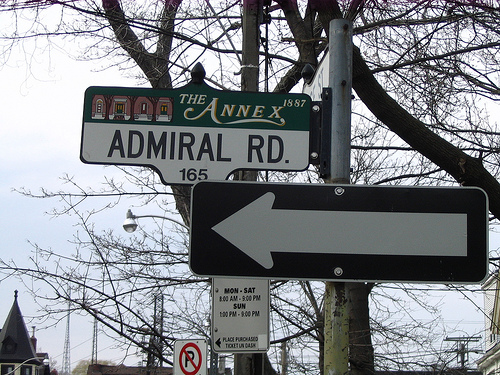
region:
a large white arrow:
[217, 194, 470, 271]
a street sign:
[78, 80, 313, 185]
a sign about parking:
[211, 278, 273, 352]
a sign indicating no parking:
[171, 340, 211, 374]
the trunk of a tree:
[319, 281, 376, 373]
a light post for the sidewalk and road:
[118, 204, 189, 241]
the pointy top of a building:
[0, 301, 42, 373]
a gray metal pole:
[321, 17, 358, 182]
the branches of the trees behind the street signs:
[25, 0, 498, 371]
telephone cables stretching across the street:
[243, 326, 480, 363]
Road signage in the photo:
[111, 100, 361, 267]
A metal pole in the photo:
[323, 72, 361, 138]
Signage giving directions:
[196, 180, 441, 270]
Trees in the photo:
[378, 25, 455, 126]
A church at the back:
[1, 281, 41, 373]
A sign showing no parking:
[165, 330, 211, 373]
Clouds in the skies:
[19, 208, 77, 268]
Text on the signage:
[115, 100, 279, 172]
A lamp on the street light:
[107, 206, 158, 241]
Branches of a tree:
[377, 33, 437, 133]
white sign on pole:
[208, 282, 274, 353]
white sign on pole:
[173, 339, 205, 374]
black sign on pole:
[187, 175, 489, 285]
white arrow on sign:
[208, 191, 478, 273]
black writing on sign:
[102, 129, 288, 164]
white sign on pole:
[79, 85, 315, 174]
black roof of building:
[0, 288, 37, 365]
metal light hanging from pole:
[121, 210, 143, 232]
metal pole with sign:
[325, 46, 347, 176]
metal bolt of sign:
[332, 187, 342, 194]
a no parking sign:
[172, 337, 209, 374]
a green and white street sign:
[77, 85, 313, 185]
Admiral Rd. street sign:
[78, 84, 312, 186]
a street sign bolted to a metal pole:
[78, 17, 350, 180]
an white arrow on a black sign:
[209, 190, 469, 270]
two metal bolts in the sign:
[332, 185, 344, 277]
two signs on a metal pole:
[78, 83, 489, 285]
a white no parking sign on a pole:
[172, 337, 207, 374]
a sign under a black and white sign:
[210, 278, 271, 353]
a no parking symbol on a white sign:
[177, 342, 202, 374]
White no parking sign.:
[173, 338, 208, 374]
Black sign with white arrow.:
[192, 179, 488, 283]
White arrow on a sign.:
[212, 192, 467, 270]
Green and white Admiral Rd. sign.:
[80, 60, 313, 178]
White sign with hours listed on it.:
[211, 273, 271, 351]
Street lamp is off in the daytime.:
[123, 208, 190, 233]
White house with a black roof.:
[0, 290, 50, 372]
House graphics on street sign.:
[90, 93, 175, 123]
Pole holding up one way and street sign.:
[324, 18, 349, 373]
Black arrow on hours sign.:
[215, 337, 222, 347]